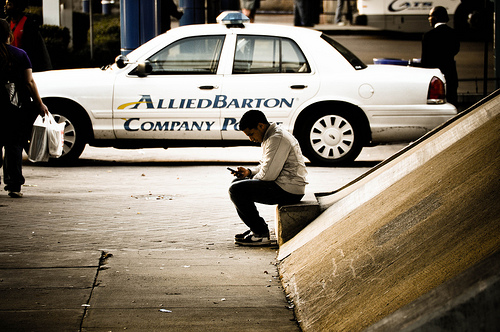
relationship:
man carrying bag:
[1, 18, 46, 195] [33, 104, 80, 169]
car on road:
[20, 8, 467, 163] [4, 143, 410, 164]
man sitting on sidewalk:
[227, 110, 307, 245] [4, 167, 380, 330]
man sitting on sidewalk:
[1, 18, 46, 195] [4, 167, 380, 330]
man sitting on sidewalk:
[419, 5, 460, 107] [4, 167, 380, 330]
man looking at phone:
[227, 110, 307, 245] [222, 161, 248, 182]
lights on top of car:
[192, 0, 256, 27] [20, 8, 462, 171]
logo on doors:
[120, 90, 297, 134] [104, 32, 331, 139]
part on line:
[75, 247, 106, 329] [77, 248, 106, 325]